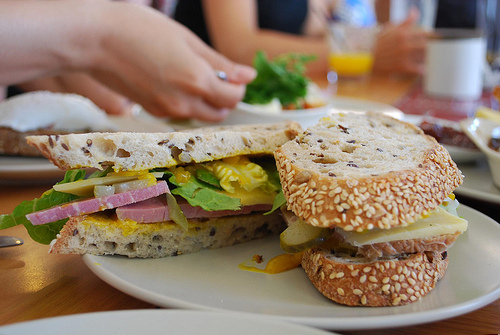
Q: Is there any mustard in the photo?
A: Yes, there is mustard.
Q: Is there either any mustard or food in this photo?
A: Yes, there is mustard.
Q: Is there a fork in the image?
A: No, there are no forks.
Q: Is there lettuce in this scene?
A: Yes, there is lettuce.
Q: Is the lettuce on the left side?
A: Yes, the lettuce is on the left of the image.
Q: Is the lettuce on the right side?
A: No, the lettuce is on the left of the image.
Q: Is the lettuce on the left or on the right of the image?
A: The lettuce is on the left of the image.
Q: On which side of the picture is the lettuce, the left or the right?
A: The lettuce is on the left of the image.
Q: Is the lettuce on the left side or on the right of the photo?
A: The lettuce is on the left of the image.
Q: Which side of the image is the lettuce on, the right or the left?
A: The lettuce is on the left of the image.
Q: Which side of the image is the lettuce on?
A: The lettuce is on the left of the image.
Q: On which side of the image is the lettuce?
A: The lettuce is on the left of the image.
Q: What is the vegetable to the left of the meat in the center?
A: The vegetable is lettuce.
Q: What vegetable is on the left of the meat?
A: The vegetable is lettuce.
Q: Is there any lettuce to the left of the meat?
A: Yes, there is lettuce to the left of the meat.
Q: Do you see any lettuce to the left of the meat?
A: Yes, there is lettuce to the left of the meat.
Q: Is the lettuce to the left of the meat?
A: Yes, the lettuce is to the left of the meat.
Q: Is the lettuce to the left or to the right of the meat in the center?
A: The lettuce is to the left of the meat.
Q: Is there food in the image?
A: Yes, there is food.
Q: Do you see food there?
A: Yes, there is food.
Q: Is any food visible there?
A: Yes, there is food.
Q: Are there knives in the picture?
A: No, there are no knives.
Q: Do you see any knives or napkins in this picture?
A: No, there are no knives or napkins.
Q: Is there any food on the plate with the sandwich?
A: Yes, there is food on the plate.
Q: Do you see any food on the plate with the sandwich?
A: Yes, there is food on the plate.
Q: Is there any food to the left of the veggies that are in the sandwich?
A: Yes, there is food to the left of the vegetables.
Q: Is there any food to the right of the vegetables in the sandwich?
A: No, the food is to the left of the vegetables.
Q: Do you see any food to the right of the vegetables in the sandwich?
A: No, the food is to the left of the vegetables.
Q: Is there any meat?
A: Yes, there is meat.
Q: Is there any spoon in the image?
A: No, there are no spoons.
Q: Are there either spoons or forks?
A: No, there are no spoons or forks.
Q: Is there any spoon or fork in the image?
A: No, there are no spoons or forks.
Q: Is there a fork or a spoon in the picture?
A: No, there are no spoons or forks.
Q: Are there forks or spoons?
A: No, there are no spoons or forks.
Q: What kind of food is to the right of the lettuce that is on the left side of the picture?
A: The food is meat.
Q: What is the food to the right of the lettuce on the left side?
A: The food is meat.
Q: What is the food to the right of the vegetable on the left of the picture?
A: The food is meat.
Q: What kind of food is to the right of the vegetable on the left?
A: The food is meat.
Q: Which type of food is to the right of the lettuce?
A: The food is meat.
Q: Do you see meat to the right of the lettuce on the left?
A: Yes, there is meat to the right of the lettuce.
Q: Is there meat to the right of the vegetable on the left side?
A: Yes, there is meat to the right of the lettuce.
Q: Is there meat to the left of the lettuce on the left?
A: No, the meat is to the right of the lettuce.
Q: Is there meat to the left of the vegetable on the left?
A: No, the meat is to the right of the lettuce.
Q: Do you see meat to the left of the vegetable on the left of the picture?
A: No, the meat is to the right of the lettuce.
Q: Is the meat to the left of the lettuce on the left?
A: No, the meat is to the right of the lettuce.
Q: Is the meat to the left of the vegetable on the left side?
A: No, the meat is to the right of the lettuce.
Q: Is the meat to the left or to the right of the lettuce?
A: The meat is to the right of the lettuce.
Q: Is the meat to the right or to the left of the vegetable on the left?
A: The meat is to the right of the lettuce.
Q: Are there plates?
A: Yes, there is a plate.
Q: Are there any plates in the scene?
A: Yes, there is a plate.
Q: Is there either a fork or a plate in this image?
A: Yes, there is a plate.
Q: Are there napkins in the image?
A: No, there are no napkins.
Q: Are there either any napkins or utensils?
A: No, there are no napkins or utensils.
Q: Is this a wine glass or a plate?
A: This is a plate.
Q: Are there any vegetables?
A: Yes, there are vegetables.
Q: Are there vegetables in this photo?
A: Yes, there are vegetables.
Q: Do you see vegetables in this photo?
A: Yes, there are vegetables.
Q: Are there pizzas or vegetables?
A: Yes, there are vegetables.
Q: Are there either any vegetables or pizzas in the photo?
A: Yes, there are vegetables.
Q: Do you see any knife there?
A: No, there are no knives.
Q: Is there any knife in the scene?
A: No, there are no knives.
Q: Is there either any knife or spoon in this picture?
A: No, there are no knives or spoons.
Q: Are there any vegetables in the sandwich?
A: Yes, there are vegetables in the sandwich.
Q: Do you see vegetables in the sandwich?
A: Yes, there are vegetables in the sandwich.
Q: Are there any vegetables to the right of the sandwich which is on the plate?
A: Yes, there are vegetables to the right of the sandwich.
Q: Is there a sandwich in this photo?
A: Yes, there is a sandwich.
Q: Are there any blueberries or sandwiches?
A: Yes, there is a sandwich.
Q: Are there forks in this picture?
A: No, there are no forks.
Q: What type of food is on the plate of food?
A: The food is a sandwich.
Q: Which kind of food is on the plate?
A: The food is a sandwich.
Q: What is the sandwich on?
A: The sandwich is on the plate.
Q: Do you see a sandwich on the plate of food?
A: Yes, there is a sandwich on the plate.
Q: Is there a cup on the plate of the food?
A: No, there is a sandwich on the plate.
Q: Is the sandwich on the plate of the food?
A: Yes, the sandwich is on the plate.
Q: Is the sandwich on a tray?
A: No, the sandwich is on the plate.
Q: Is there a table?
A: Yes, there is a table.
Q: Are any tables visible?
A: Yes, there is a table.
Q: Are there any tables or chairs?
A: Yes, there is a table.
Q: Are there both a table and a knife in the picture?
A: No, there is a table but no knives.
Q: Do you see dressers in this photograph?
A: No, there are no dressers.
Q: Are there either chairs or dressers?
A: No, there are no dressers or chairs.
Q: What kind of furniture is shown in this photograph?
A: The furniture is a table.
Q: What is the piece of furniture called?
A: The piece of furniture is a table.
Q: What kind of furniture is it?
A: The piece of furniture is a table.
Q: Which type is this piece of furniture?
A: That is a table.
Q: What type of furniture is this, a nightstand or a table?
A: That is a table.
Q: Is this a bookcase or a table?
A: This is a table.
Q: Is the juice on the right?
A: Yes, the juice is on the right of the image.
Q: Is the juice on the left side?
A: No, the juice is on the right of the image.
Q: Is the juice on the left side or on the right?
A: The juice is on the right of the image.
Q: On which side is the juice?
A: The juice is on the right of the image.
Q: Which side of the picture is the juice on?
A: The juice is on the right of the image.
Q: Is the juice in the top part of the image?
A: Yes, the juice is in the top of the image.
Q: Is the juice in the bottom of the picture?
A: No, the juice is in the top of the image.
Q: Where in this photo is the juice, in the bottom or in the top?
A: The juice is in the top of the image.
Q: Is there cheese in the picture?
A: Yes, there is cheese.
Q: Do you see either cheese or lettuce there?
A: Yes, there is cheese.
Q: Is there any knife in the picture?
A: No, there are no knives.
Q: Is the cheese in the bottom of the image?
A: Yes, the cheese is in the bottom of the image.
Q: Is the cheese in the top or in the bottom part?
A: The cheese is in the bottom of the image.